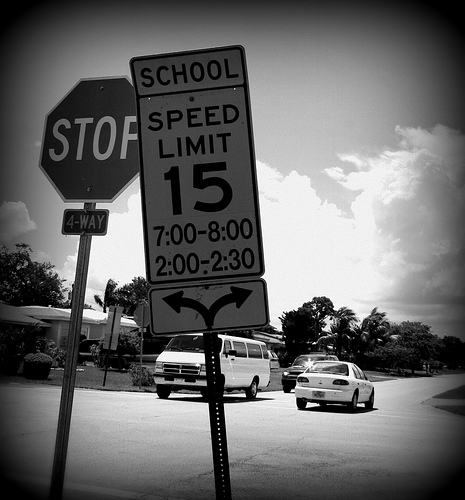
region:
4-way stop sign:
[34, 72, 138, 233]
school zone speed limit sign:
[131, 44, 272, 331]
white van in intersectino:
[154, 330, 270, 398]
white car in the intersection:
[296, 362, 373, 413]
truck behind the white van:
[283, 351, 336, 386]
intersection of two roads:
[8, 396, 461, 490]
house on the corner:
[3, 308, 145, 369]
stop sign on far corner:
[132, 307, 150, 330]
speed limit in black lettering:
[149, 107, 240, 214]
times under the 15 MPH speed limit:
[152, 220, 256, 273]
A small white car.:
[293, 358, 374, 413]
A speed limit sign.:
[139, 93, 267, 279]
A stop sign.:
[38, 75, 140, 204]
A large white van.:
[157, 334, 269, 401]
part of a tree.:
[375, 343, 413, 360]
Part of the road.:
[252, 422, 302, 455]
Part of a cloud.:
[384, 198, 445, 249]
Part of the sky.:
[311, 59, 378, 119]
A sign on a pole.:
[99, 305, 120, 387]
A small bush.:
[22, 353, 52, 378]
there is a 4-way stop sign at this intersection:
[35, 69, 142, 238]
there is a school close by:
[129, 40, 257, 99]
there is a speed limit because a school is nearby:
[129, 44, 263, 222]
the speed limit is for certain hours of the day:
[138, 97, 272, 283]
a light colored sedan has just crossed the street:
[293, 358, 378, 408]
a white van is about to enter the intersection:
[148, 327, 270, 401]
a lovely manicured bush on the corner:
[20, 349, 55, 380]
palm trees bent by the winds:
[315, 302, 396, 367]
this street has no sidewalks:
[371, 364, 463, 408]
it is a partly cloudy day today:
[256, 52, 462, 312]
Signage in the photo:
[129, 51, 265, 321]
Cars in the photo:
[154, 323, 375, 419]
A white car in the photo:
[287, 353, 374, 416]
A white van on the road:
[154, 334, 290, 397]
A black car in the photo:
[283, 344, 333, 387]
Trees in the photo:
[333, 314, 421, 366]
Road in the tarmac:
[264, 399, 374, 465]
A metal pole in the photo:
[186, 353, 256, 478]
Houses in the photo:
[11, 288, 60, 355]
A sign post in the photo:
[103, 298, 118, 386]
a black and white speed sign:
[103, 36, 285, 409]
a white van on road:
[146, 310, 274, 395]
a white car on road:
[274, 337, 406, 440]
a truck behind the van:
[275, 350, 348, 394]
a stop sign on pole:
[21, 59, 146, 262]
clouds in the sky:
[69, 132, 462, 320]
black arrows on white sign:
[155, 278, 316, 347]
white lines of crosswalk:
[221, 377, 445, 432]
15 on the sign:
[153, 152, 244, 227]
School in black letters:
[138, 62, 253, 89]